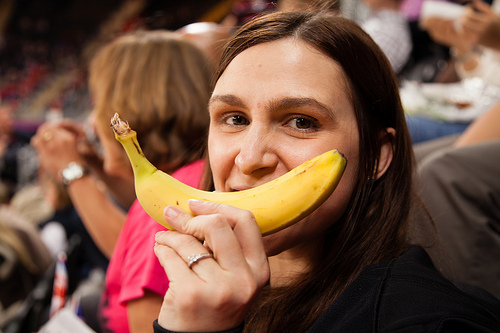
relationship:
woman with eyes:
[149, 9, 476, 332] [207, 97, 328, 134]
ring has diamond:
[184, 248, 214, 268] [189, 255, 199, 260]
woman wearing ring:
[149, 9, 476, 332] [184, 248, 214, 268]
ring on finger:
[184, 248, 214, 268] [152, 200, 270, 300]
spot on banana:
[171, 200, 192, 212] [109, 109, 352, 241]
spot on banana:
[176, 200, 179, 206] [109, 109, 352, 241]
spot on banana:
[303, 175, 324, 196] [109, 109, 352, 241]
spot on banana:
[290, 164, 311, 178] [109, 109, 352, 241]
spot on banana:
[127, 132, 147, 160] [109, 109, 352, 241]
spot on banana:
[111, 135, 129, 142] [109, 109, 352, 241]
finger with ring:
[146, 220, 211, 279] [184, 248, 214, 268]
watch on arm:
[48, 153, 100, 187] [151, 202, 269, 329]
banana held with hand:
[109, 109, 352, 241] [142, 185, 271, 330]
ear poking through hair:
[369, 121, 397, 182] [214, 3, 418, 327]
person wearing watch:
[30, 20, 118, 260] [49, 147, 94, 195]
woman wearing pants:
[149, 9, 476, 332] [406, 120, 482, 287]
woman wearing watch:
[149, 9, 476, 332] [55, 150, 100, 189]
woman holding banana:
[112, 2, 475, 325] [109, 109, 352, 241]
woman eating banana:
[149, 9, 476, 332] [89, 102, 355, 249]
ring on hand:
[184, 248, 214, 268] [22, 110, 91, 179]